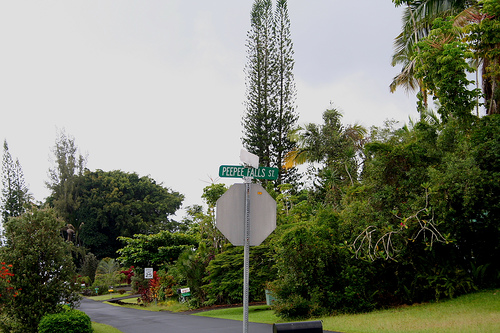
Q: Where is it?
A: This is at the forest.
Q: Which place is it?
A: It is a forest.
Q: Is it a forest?
A: Yes, it is a forest.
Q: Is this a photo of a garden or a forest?
A: It is showing a forest.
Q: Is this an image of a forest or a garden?
A: It is showing a forest.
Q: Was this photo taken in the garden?
A: No, the picture was taken in the forest.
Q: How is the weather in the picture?
A: It is overcast.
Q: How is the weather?
A: It is overcast.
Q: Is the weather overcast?
A: Yes, it is overcast.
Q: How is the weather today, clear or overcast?
A: It is overcast.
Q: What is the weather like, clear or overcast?
A: It is overcast.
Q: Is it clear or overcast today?
A: It is overcast.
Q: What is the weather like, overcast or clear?
A: It is overcast.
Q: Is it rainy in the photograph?
A: No, it is overcast.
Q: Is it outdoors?
A: Yes, it is outdoors.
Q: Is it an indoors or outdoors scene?
A: It is outdoors.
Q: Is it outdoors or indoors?
A: It is outdoors.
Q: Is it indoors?
A: No, it is outdoors.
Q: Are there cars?
A: No, there are no cars.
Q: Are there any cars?
A: No, there are no cars.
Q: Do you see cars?
A: No, there are no cars.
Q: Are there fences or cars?
A: No, there are no cars or fences.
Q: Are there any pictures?
A: No, there are no pictures.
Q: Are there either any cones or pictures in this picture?
A: No, there are no pictures or cones.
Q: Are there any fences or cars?
A: No, there are no cars or fences.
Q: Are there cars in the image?
A: No, there are no cars.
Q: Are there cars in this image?
A: No, there are no cars.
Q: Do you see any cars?
A: No, there are no cars.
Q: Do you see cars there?
A: No, there are no cars.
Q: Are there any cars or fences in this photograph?
A: No, there are no cars or fences.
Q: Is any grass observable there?
A: Yes, there is grass.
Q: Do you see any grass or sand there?
A: Yes, there is grass.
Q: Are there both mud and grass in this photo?
A: No, there is grass but no mud.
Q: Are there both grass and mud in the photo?
A: No, there is grass but no mud.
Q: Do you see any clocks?
A: No, there are no clocks.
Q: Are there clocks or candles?
A: No, there are no clocks or candles.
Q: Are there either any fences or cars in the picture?
A: No, there are no fences or cars.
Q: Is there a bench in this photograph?
A: No, there are no benches.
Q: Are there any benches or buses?
A: No, there are no benches or buses.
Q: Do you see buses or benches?
A: No, there are no benches or buses.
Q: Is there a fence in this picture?
A: No, there are no fences.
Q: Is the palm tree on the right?
A: Yes, the palm tree is on the right of the image.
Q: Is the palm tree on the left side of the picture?
A: No, the palm tree is on the right of the image.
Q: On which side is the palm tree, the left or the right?
A: The palm tree is on the right of the image.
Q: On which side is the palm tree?
A: The palm tree is on the right of the image.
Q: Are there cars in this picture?
A: No, there are no cars.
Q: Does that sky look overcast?
A: Yes, the sky is overcast.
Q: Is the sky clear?
A: No, the sky is overcast.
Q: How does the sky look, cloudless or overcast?
A: The sky is overcast.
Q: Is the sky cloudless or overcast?
A: The sky is overcast.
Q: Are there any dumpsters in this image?
A: No, there are no dumpsters.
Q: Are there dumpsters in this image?
A: No, there are no dumpsters.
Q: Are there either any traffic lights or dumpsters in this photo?
A: No, there are no dumpsters or traffic lights.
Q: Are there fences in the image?
A: No, there are no fences.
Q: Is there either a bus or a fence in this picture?
A: No, there are no fences or buses.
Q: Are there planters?
A: No, there are no planters.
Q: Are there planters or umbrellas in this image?
A: No, there are no planters or umbrellas.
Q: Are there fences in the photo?
A: No, there are no fences.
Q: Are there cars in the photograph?
A: No, there are no cars.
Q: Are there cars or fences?
A: No, there are no cars or fences.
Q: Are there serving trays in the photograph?
A: No, there are no serving trays.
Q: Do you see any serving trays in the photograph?
A: No, there are no serving trays.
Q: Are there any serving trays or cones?
A: No, there are no serving trays or cones.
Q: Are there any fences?
A: No, there are no fences.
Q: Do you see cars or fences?
A: No, there are no fences or cars.